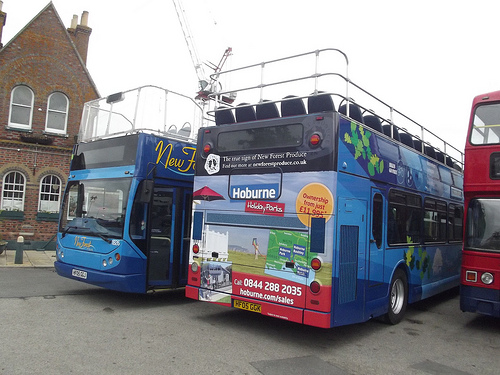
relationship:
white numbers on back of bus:
[232, 277, 302, 295] [186, 44, 461, 332]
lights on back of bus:
[300, 254, 326, 303] [186, 44, 461, 332]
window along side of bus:
[387, 190, 464, 245] [186, 44, 461, 332]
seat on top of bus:
[308, 90, 336, 113] [186, 44, 461, 332]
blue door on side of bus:
[366, 187, 387, 301] [186, 44, 461, 332]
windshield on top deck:
[75, 84, 202, 141] [68, 130, 198, 172]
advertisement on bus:
[189, 149, 337, 176] [186, 44, 461, 332]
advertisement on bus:
[187, 170, 337, 327] [186, 44, 461, 332]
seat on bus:
[210, 106, 236, 125] [186, 44, 461, 332]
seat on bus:
[255, 100, 281, 121] [186, 44, 461, 332]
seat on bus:
[307, 89, 337, 113] [186, 44, 461, 332]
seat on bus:
[360, 107, 384, 132] [186, 44, 461, 332]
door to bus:
[146, 174, 191, 290] [53, 84, 202, 295]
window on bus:
[387, 188, 467, 246] [186, 44, 461, 332]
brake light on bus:
[198, 114, 331, 154] [186, 44, 461, 332]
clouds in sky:
[98, 0, 500, 56] [1, 1, 498, 98]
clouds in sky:
[195, 9, 286, 43] [1, 1, 498, 98]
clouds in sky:
[98, 0, 500, 56] [1, 1, 497, 116]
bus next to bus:
[53, 84, 202, 295] [186, 44, 461, 332]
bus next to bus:
[459, 87, 499, 318] [186, 44, 461, 332]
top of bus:
[193, 47, 464, 194] [186, 44, 461, 332]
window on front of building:
[7, 81, 36, 131] [0, 0, 100, 249]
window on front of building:
[45, 90, 73, 137] [0, 0, 100, 249]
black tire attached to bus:
[378, 268, 408, 325] [186, 44, 461, 332]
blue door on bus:
[366, 187, 387, 301] [186, 44, 461, 332]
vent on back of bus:
[336, 220, 361, 305] [186, 44, 461, 332]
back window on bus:
[208, 120, 304, 159] [186, 44, 461, 332]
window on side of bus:
[387, 190, 464, 245] [186, 44, 461, 332]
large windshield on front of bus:
[59, 177, 132, 237] [50, 83, 192, 298]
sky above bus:
[1, 1, 497, 116] [186, 47, 465, 332]